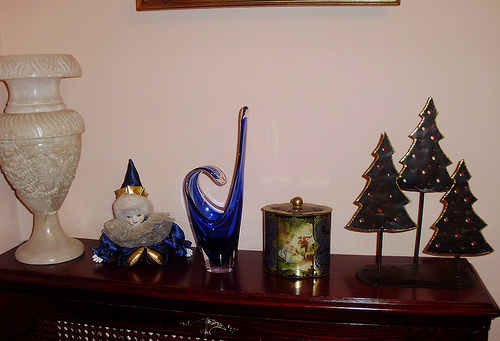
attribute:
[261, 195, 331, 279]
container — blue, gold, painted, small, multicolored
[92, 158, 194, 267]
doll — porcelain, clown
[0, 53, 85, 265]
vase — marble, beige, white, large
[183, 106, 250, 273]
sculpture — blue, glass, blown glass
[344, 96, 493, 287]
tree decoration — metal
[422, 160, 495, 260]
tree — green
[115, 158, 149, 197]
hat — blue, gold, small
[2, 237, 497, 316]
table — wooden, brown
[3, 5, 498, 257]
wall — white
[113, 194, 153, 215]
hair — white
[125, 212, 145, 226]
face — white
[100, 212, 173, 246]
collar — sheer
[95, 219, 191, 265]
outfit — blue